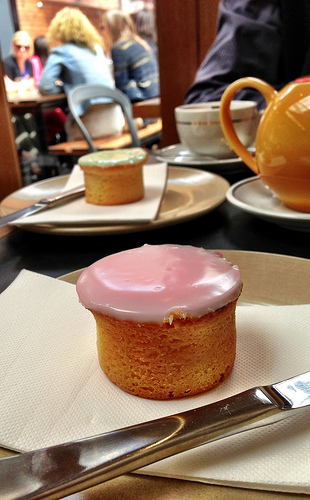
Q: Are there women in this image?
A: Yes, there is a woman.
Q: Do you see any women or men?
A: Yes, there is a woman.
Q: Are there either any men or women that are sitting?
A: Yes, the woman is sitting.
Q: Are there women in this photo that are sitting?
A: Yes, there is a woman that is sitting.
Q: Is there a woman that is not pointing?
A: Yes, there is a woman that is sitting.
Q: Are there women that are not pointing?
A: Yes, there is a woman that is sitting.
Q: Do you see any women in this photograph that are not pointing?
A: Yes, there is a woman that is sitting .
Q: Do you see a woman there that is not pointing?
A: Yes, there is a woman that is sitting .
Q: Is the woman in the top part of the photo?
A: Yes, the woman is in the top of the image.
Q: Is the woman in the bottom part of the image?
A: No, the woman is in the top of the image.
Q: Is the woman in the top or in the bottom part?
A: The woman is in the top of the image.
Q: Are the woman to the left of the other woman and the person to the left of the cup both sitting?
A: Yes, both the woman and the person are sitting.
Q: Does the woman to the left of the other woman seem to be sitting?
A: Yes, the woman is sitting.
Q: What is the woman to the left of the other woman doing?
A: The woman is sitting.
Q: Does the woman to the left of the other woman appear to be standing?
A: No, the woman is sitting.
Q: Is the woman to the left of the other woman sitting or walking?
A: The woman is sitting.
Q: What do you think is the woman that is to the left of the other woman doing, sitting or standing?
A: The woman is sitting.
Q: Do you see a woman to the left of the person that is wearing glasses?
A: Yes, there is a woman to the left of the person.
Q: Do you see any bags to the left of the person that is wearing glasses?
A: No, there is a woman to the left of the person.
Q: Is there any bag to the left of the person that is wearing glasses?
A: No, there is a woman to the left of the person.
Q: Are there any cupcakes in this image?
A: Yes, there is a cupcake.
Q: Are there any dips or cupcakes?
A: Yes, there is a cupcake.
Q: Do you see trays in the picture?
A: No, there are no trays.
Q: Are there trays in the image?
A: No, there are no trays.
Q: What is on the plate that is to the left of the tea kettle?
A: The cupcake is on the plate.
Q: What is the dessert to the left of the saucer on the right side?
A: The dessert is a cupcake.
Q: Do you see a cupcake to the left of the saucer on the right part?
A: Yes, there is a cupcake to the left of the saucer.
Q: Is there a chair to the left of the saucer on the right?
A: No, there is a cupcake to the left of the saucer.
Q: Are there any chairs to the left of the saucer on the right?
A: No, there is a cupcake to the left of the saucer.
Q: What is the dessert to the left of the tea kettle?
A: The dessert is a cupcake.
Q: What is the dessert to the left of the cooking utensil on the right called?
A: The dessert is a cupcake.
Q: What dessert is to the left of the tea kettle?
A: The dessert is a cupcake.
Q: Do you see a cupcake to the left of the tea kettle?
A: Yes, there is a cupcake to the left of the tea kettle.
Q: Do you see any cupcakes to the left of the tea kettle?
A: Yes, there is a cupcake to the left of the tea kettle.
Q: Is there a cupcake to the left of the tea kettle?
A: Yes, there is a cupcake to the left of the tea kettle.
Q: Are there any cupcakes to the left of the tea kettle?
A: Yes, there is a cupcake to the left of the tea kettle.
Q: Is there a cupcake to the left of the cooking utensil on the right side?
A: Yes, there is a cupcake to the left of the tea kettle.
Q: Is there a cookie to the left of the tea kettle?
A: No, there is a cupcake to the left of the tea kettle.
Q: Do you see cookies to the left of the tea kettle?
A: No, there is a cupcake to the left of the tea kettle.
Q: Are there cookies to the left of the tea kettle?
A: No, there is a cupcake to the left of the tea kettle.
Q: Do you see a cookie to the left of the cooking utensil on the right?
A: No, there is a cupcake to the left of the tea kettle.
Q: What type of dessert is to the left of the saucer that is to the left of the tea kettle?
A: The dessert is a cupcake.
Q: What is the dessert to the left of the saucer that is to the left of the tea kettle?
A: The dessert is a cupcake.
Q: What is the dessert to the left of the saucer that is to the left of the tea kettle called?
A: The dessert is a cupcake.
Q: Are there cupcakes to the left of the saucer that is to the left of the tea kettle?
A: Yes, there is a cupcake to the left of the saucer.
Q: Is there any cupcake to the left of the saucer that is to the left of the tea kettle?
A: Yes, there is a cupcake to the left of the saucer.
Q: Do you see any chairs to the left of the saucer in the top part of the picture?
A: No, there is a cupcake to the left of the saucer.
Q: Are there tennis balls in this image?
A: No, there are no tennis balls.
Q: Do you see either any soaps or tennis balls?
A: No, there are no tennis balls or soaps.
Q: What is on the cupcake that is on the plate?
A: The frosting is on the cupcake.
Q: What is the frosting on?
A: The frosting is on the cupcake.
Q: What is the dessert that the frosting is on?
A: The dessert is a cupcake.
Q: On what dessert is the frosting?
A: The frosting is on the cupcake.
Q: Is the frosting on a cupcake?
A: Yes, the frosting is on a cupcake.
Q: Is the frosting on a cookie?
A: No, the frosting is on a cupcake.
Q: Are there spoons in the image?
A: No, there are no spoons.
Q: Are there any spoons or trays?
A: No, there are no spoons or trays.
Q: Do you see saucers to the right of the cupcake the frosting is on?
A: Yes, there is a saucer to the right of the cupcake.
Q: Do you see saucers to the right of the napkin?
A: Yes, there is a saucer to the right of the napkin.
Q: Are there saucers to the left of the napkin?
A: No, the saucer is to the right of the napkin.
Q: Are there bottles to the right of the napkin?
A: No, there is a saucer to the right of the napkin.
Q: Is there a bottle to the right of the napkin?
A: No, there is a saucer to the right of the napkin.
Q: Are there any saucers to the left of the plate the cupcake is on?
A: No, the saucer is to the right of the plate.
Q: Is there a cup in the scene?
A: Yes, there is a cup.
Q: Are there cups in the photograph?
A: Yes, there is a cup.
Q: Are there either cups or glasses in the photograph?
A: Yes, there is a cup.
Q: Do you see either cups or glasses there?
A: Yes, there is a cup.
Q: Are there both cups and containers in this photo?
A: No, there is a cup but no containers.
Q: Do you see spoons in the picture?
A: No, there are no spoons.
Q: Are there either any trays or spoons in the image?
A: No, there are no spoons or trays.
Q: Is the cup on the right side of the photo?
A: Yes, the cup is on the right of the image.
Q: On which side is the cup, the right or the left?
A: The cup is on the right of the image.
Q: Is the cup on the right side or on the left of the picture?
A: The cup is on the right of the image.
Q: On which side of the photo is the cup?
A: The cup is on the right of the image.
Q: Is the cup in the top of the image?
A: Yes, the cup is in the top of the image.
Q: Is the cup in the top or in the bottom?
A: The cup is in the top of the image.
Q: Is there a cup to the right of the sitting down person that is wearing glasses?
A: Yes, there is a cup to the right of the person.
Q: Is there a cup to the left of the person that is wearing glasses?
A: No, the cup is to the right of the person.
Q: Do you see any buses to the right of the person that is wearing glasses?
A: No, there is a cup to the right of the person.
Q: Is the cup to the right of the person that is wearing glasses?
A: Yes, the cup is to the right of the person.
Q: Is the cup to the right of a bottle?
A: No, the cup is to the right of the person.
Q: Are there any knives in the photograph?
A: Yes, there is a knife.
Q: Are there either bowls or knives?
A: Yes, there is a knife.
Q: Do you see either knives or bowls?
A: Yes, there is a knife.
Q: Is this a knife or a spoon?
A: This is a knife.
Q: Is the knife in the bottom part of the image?
A: Yes, the knife is in the bottom of the image.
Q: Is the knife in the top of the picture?
A: No, the knife is in the bottom of the image.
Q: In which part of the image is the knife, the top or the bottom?
A: The knife is in the bottom of the image.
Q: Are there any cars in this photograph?
A: No, there are no cars.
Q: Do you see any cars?
A: No, there are no cars.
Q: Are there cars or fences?
A: No, there are no cars or fences.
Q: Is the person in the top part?
A: Yes, the person is in the top of the image.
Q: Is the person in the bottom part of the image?
A: No, the person is in the top of the image.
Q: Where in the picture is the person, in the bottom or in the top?
A: The person is in the top of the image.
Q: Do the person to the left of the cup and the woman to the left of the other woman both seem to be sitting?
A: Yes, both the person and the woman are sitting.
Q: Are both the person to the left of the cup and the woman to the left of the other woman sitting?
A: Yes, both the person and the woman are sitting.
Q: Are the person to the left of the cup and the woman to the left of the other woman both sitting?
A: Yes, both the person and the woman are sitting.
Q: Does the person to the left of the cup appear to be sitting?
A: Yes, the person is sitting.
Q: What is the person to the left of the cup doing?
A: The person is sitting.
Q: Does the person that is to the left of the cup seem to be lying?
A: No, the person is sitting.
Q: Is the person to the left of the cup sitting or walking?
A: The person is sitting.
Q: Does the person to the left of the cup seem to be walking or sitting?
A: The person is sitting.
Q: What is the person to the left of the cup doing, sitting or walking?
A: The person is sitting.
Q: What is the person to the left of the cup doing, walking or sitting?
A: The person is sitting.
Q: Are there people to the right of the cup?
A: No, the person is to the left of the cup.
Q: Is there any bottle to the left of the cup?
A: No, there is a person to the left of the cup.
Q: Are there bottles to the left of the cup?
A: No, there is a person to the left of the cup.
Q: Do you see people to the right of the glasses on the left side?
A: Yes, there is a person to the right of the glasses.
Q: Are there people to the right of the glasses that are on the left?
A: Yes, there is a person to the right of the glasses.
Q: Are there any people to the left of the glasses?
A: No, the person is to the right of the glasses.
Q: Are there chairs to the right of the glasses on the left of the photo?
A: No, there is a person to the right of the glasses.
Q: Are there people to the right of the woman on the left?
A: Yes, there is a person to the right of the woman.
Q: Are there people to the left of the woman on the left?
A: No, the person is to the right of the woman.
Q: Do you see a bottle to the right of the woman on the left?
A: No, there is a person to the right of the woman.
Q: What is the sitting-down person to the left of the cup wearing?
A: The person is wearing glasses.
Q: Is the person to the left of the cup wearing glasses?
A: Yes, the person is wearing glasses.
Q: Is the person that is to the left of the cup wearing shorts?
A: No, the person is wearing glasses.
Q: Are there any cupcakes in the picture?
A: Yes, there is a cupcake.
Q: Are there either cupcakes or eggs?
A: Yes, there is a cupcake.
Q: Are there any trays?
A: No, there are no trays.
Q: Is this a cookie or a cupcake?
A: This is a cupcake.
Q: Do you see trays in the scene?
A: No, there are no trays.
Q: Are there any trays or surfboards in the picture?
A: No, there are no trays or surfboards.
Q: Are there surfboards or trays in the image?
A: No, there are no trays or surfboards.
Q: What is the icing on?
A: The icing is on the cupcake.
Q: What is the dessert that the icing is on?
A: The dessert is a cupcake.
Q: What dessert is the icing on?
A: The icing is on the cupcake.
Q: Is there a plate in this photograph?
A: Yes, there is a plate.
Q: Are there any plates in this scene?
A: Yes, there is a plate.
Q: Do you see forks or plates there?
A: Yes, there is a plate.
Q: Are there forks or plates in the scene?
A: Yes, there is a plate.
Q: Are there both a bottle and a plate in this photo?
A: No, there is a plate but no bottles.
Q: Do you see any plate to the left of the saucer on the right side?
A: Yes, there is a plate to the left of the saucer.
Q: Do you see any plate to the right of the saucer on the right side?
A: No, the plate is to the left of the saucer.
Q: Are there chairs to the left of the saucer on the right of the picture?
A: No, there is a plate to the left of the saucer.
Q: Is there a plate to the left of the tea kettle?
A: Yes, there is a plate to the left of the tea kettle.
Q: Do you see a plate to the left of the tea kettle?
A: Yes, there is a plate to the left of the tea kettle.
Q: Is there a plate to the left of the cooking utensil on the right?
A: Yes, there is a plate to the left of the tea kettle.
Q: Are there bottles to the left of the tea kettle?
A: No, there is a plate to the left of the tea kettle.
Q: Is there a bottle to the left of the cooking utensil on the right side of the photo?
A: No, there is a plate to the left of the tea kettle.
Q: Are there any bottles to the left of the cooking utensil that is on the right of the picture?
A: No, there is a plate to the left of the tea kettle.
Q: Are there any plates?
A: Yes, there is a plate.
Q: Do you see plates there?
A: Yes, there is a plate.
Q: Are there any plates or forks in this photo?
A: Yes, there is a plate.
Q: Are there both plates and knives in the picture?
A: Yes, there are both a plate and a knife.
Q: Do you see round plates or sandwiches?
A: Yes, there is a round plate.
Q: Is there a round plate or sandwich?
A: Yes, there is a round plate.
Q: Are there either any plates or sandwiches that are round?
A: Yes, the plate is round.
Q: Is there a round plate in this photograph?
A: Yes, there is a round plate.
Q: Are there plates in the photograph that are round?
A: Yes, there is a plate that is round.